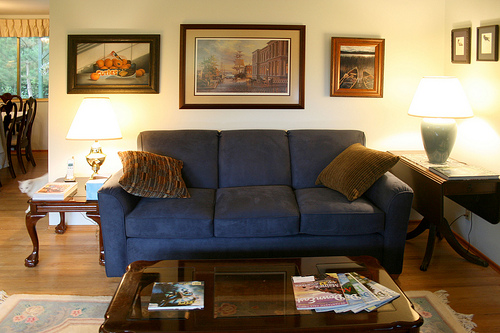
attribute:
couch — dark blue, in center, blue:
[98, 128, 411, 277]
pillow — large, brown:
[116, 148, 193, 200]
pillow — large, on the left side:
[315, 143, 402, 200]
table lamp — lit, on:
[71, 96, 125, 179]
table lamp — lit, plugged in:
[403, 75, 471, 168]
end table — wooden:
[24, 170, 112, 269]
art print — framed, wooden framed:
[176, 23, 305, 112]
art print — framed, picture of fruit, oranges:
[65, 34, 165, 97]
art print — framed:
[329, 35, 385, 101]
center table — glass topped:
[104, 257, 424, 330]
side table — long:
[385, 145, 498, 274]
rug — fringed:
[3, 285, 476, 332]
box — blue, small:
[84, 179, 105, 201]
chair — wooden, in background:
[1, 92, 23, 112]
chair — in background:
[19, 99, 35, 168]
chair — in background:
[0, 101, 18, 181]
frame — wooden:
[329, 34, 387, 101]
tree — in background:
[20, 37, 54, 98]